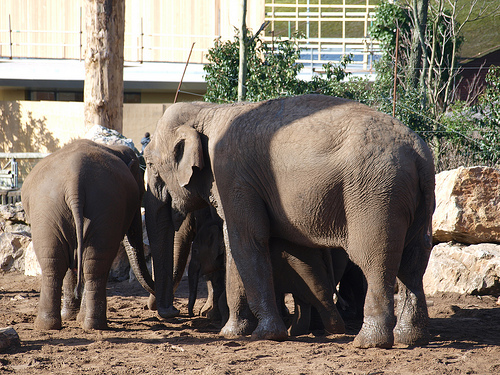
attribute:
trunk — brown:
[138, 194, 185, 324]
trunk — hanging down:
[140, 184, 185, 327]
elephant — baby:
[181, 97, 471, 351]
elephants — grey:
[37, 72, 471, 357]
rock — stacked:
[433, 165, 498, 245]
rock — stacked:
[420, 240, 498, 317]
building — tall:
[259, 1, 392, 87]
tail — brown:
[59, 180, 98, 309]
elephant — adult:
[136, 93, 457, 358]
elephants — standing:
[0, 85, 448, 335]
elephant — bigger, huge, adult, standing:
[144, 97, 437, 348]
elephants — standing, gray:
[22, 87, 440, 345]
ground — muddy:
[2, 268, 499, 368]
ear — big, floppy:
[161, 122, 210, 196]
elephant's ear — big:
[167, 125, 207, 199]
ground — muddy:
[52, 347, 492, 373]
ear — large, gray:
[172, 119, 212, 194]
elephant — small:
[18, 135, 155, 333]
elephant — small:
[18, 131, 153, 355]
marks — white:
[360, 317, 387, 333]